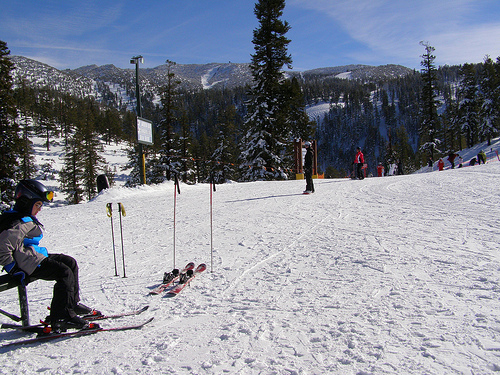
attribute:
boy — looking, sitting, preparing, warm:
[0, 179, 94, 334]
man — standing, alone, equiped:
[301, 140, 314, 195]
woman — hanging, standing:
[354, 146, 366, 180]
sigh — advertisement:
[133, 116, 157, 147]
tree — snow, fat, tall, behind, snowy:
[244, 0, 298, 179]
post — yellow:
[135, 52, 148, 184]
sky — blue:
[0, 1, 499, 69]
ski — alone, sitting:
[164, 262, 207, 300]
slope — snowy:
[1, 162, 500, 374]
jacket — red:
[353, 153, 365, 166]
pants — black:
[33, 253, 98, 316]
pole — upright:
[207, 168, 217, 283]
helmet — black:
[13, 178, 50, 214]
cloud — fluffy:
[393, 14, 499, 64]